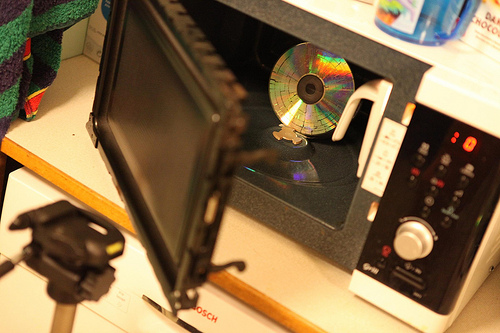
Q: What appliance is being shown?
A: Microwave.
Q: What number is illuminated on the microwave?
A: 0.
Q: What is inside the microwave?
A: Disk.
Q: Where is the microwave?
A: Counter top.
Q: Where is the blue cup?
A: Top of microwave.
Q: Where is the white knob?
A: Control panel of the microwave.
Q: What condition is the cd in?
A: Cracked.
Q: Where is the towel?
A: Top left side of the image.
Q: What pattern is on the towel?
A: Stripes.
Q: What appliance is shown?
A: Microwave.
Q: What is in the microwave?
A: A cd and a mug.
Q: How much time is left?
A: 0 SECONDS.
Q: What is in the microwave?
A: A cd.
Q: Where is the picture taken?
A: A kitchen.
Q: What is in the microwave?
A: A cd.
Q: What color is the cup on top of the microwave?
A: Blue.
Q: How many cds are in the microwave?
A: One.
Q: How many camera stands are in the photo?
A: One.